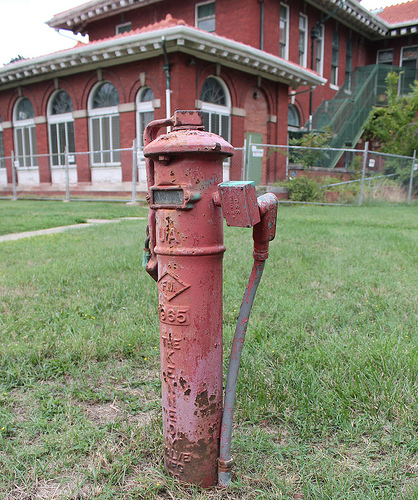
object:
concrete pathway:
[0, 215, 143, 241]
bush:
[269, 174, 318, 202]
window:
[198, 75, 231, 164]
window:
[136, 86, 157, 147]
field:
[9, 192, 416, 470]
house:
[0, 0, 418, 199]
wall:
[228, 2, 411, 183]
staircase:
[288, 64, 418, 169]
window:
[85, 79, 119, 166]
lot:
[2, 198, 412, 400]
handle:
[142, 117, 173, 282]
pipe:
[218, 247, 269, 487]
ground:
[0, 199, 418, 500]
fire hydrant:
[143, 108, 276, 490]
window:
[12, 100, 38, 169]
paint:
[165, 314, 215, 422]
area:
[140, 284, 299, 466]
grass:
[325, 225, 363, 280]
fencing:
[0, 135, 418, 205]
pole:
[10, 150, 17, 201]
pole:
[65, 146, 70, 201]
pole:
[132, 140, 136, 202]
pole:
[358, 140, 369, 204]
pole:
[407, 148, 416, 205]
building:
[0, 0, 418, 200]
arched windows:
[12, 80, 154, 128]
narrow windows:
[0, 111, 154, 168]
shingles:
[4, 13, 321, 77]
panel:
[153, 191, 183, 204]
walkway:
[0, 215, 146, 242]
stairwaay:
[289, 64, 418, 168]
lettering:
[160, 308, 186, 324]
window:
[46, 88, 74, 167]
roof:
[0, 0, 418, 86]